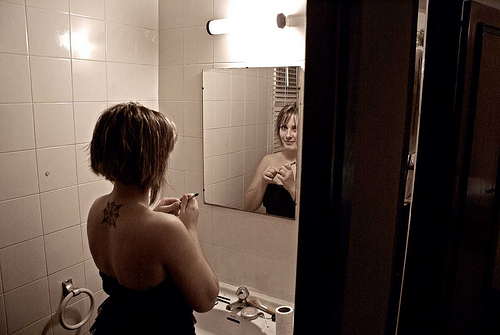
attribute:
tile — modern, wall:
[30, 104, 77, 145]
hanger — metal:
[56, 286, 97, 329]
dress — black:
[88, 265, 197, 334]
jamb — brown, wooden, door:
[343, 1, 421, 331]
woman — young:
[68, 91, 246, 325]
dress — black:
[94, 267, 197, 331]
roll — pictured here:
[274, 305, 294, 333]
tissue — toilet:
[268, 295, 292, 326]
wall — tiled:
[0, 0, 200, 320]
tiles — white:
[45, 27, 130, 105]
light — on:
[202, 10, 231, 38]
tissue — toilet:
[273, 303, 296, 331]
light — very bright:
[199, 15, 231, 40]